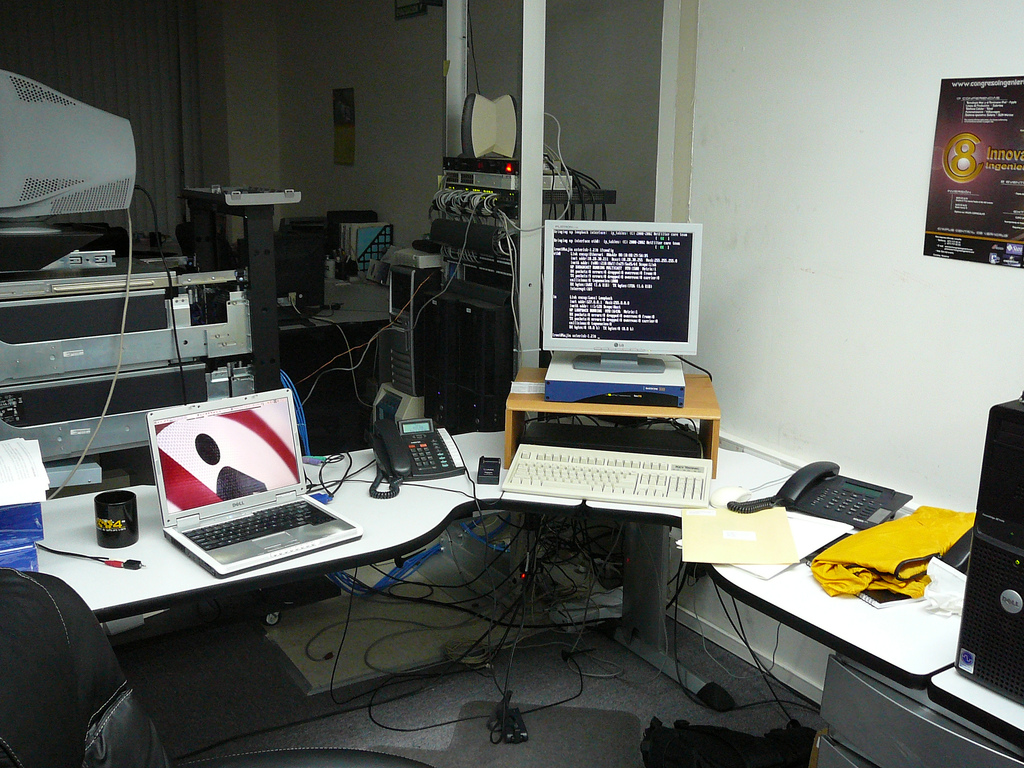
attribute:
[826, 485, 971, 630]
fabric — folded, yellow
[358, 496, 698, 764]
wires — jumbled up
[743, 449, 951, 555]
telephone — office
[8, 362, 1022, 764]
desk — convenient, corner style, computer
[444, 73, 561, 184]
speakers — dual sided audio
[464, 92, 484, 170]
facing — gray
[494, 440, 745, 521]
keyboard — white, full size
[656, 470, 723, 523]
pad — number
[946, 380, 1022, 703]
tower — Dell computer, black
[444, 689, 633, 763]
protector — plastic, computer chair, floor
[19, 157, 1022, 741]
data — electronic , office equipment, storing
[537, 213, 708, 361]
monitor — white framed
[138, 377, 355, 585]
laptop — office, working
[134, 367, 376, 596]
laptop — silver, black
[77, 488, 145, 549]
mug — black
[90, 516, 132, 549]
writing — yellow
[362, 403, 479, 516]
telephone — corded, black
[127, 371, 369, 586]
laptop — open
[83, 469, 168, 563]
mug — black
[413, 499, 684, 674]
wires — several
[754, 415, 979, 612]
phone — black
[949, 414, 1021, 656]
computer tower — black